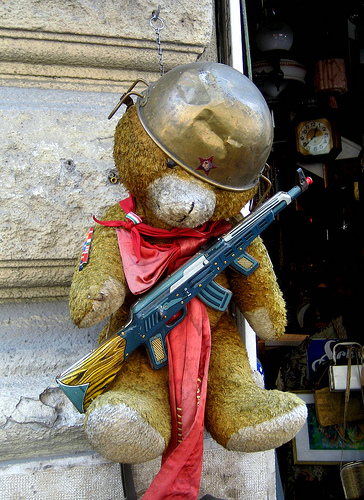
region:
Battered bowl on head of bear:
[124, 60, 281, 192]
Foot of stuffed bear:
[211, 386, 307, 451]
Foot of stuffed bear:
[82, 388, 171, 464]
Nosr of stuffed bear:
[171, 204, 202, 224]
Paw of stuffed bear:
[70, 274, 124, 329]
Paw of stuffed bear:
[242, 302, 297, 332]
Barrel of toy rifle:
[235, 172, 336, 230]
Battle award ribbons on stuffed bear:
[76, 224, 98, 272]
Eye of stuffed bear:
[161, 155, 178, 171]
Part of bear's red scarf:
[98, 194, 158, 268]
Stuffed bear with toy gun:
[50, 166, 323, 419]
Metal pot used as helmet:
[104, 52, 278, 225]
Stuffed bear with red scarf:
[68, 33, 316, 324]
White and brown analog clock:
[291, 106, 343, 158]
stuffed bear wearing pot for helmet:
[75, 55, 291, 242]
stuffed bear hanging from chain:
[120, 1, 276, 265]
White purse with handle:
[319, 332, 363, 402]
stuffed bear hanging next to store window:
[59, 10, 359, 261]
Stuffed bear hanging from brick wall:
[38, 2, 316, 338]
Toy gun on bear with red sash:
[52, 177, 322, 403]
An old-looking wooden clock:
[288, 113, 343, 161]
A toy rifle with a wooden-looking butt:
[55, 167, 312, 414]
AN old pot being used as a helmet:
[105, 60, 270, 212]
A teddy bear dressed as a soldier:
[68, 60, 310, 462]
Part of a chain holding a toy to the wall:
[150, 4, 168, 78]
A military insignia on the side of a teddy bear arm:
[77, 226, 94, 270]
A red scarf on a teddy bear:
[92, 196, 233, 498]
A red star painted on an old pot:
[195, 155, 216, 175]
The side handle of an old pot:
[107, 77, 149, 120]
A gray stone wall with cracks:
[0, 0, 277, 499]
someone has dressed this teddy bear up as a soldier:
[66, 54, 315, 464]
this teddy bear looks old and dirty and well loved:
[65, 59, 310, 467]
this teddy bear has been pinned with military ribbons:
[73, 220, 96, 271]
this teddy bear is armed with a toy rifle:
[52, 162, 319, 417]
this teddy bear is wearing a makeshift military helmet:
[103, 55, 278, 195]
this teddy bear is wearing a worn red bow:
[89, 188, 234, 497]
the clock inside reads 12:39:
[288, 104, 345, 166]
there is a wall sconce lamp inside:
[249, 1, 299, 88]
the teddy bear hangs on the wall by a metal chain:
[146, 3, 172, 84]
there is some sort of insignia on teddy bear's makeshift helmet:
[192, 152, 220, 179]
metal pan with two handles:
[109, 61, 276, 207]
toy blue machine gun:
[56, 168, 312, 412]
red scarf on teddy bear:
[69, 62, 310, 465]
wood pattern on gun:
[60, 336, 126, 412]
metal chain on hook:
[151, 4, 165, 76]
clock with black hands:
[298, 120, 330, 153]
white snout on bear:
[144, 176, 216, 225]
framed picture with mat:
[290, 388, 356, 464]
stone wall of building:
[1, 3, 216, 496]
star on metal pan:
[196, 155, 217, 175]